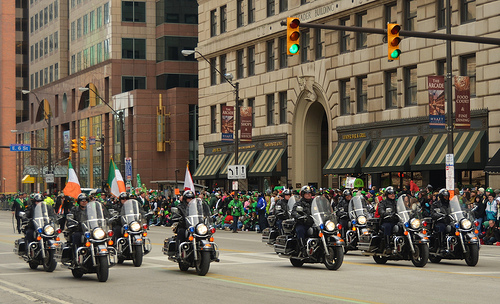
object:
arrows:
[226, 166, 233, 176]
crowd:
[0, 185, 499, 241]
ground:
[0, 207, 499, 303]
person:
[68, 193, 96, 256]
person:
[173, 188, 207, 240]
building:
[21, 0, 199, 199]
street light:
[180, 49, 197, 58]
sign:
[8, 143, 33, 153]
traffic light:
[285, 15, 300, 56]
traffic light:
[382, 21, 402, 63]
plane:
[153, 93, 171, 153]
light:
[288, 43, 301, 55]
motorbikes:
[160, 197, 219, 276]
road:
[0, 206, 499, 304]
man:
[288, 186, 317, 259]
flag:
[60, 158, 83, 198]